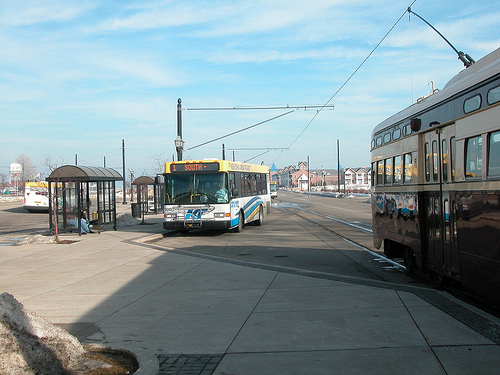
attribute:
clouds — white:
[79, 22, 417, 102]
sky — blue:
[7, 11, 450, 154]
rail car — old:
[369, 30, 498, 330]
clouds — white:
[0, 0, 497, 181]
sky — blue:
[0, 0, 498, 185]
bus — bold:
[164, 158, 280, 233]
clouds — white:
[105, 54, 164, 88]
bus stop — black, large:
[52, 157, 139, 244]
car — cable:
[323, 43, 498, 306]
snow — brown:
[0, 292, 80, 374]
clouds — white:
[3, 3, 498, 149]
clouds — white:
[1, 1, 103, 29]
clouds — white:
[79, 0, 256, 32]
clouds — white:
[176, 0, 351, 38]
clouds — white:
[4, 38, 189, 92]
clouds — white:
[156, 37, 373, 64]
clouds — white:
[0, 70, 186, 125]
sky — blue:
[78, 22, 243, 131]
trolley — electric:
[363, 44, 496, 335]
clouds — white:
[35, 32, 178, 101]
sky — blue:
[142, 24, 434, 81]